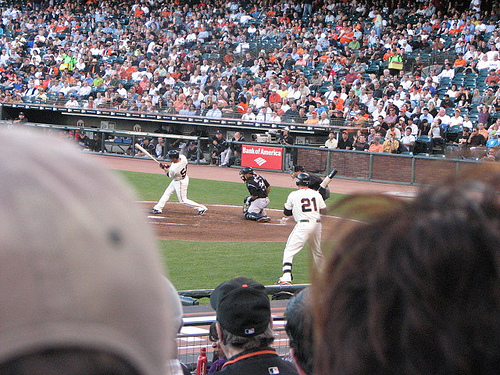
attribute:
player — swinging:
[132, 139, 212, 213]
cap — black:
[208, 275, 298, 340]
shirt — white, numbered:
[262, 183, 350, 236]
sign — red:
[234, 142, 286, 169]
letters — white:
[240, 146, 280, 156]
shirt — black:
[239, 173, 269, 202]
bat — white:
[130, 140, 168, 175]